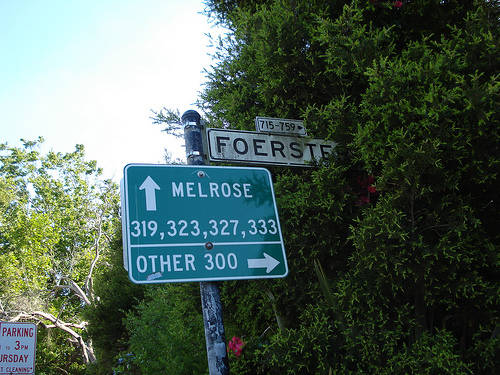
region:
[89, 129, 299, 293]
Large green sign on the pole.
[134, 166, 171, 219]
White arrow on the sign.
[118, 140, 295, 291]
Green sign with white letters.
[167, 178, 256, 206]
White letters on a green sign.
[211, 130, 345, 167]
White sign with black letters.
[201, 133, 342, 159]
Black letters on a white sign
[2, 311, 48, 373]
White sign with red letters.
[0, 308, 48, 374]
Red letters on a white sign.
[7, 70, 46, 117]
Bright blue sky high above.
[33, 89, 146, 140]
Some white clouds in the sky.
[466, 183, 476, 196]
part of a bush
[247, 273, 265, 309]
edge of a post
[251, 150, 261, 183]
part of a sign post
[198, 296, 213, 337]
edge of a post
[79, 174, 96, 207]
part of a cloud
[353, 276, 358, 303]
part of a petal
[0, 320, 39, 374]
red and white parking sign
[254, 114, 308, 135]
white and black street sign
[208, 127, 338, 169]
white and black street sign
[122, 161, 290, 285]
green and white street sign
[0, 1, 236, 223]
partly cloudy blue sky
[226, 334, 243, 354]
pink object on tree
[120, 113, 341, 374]
street signs on a metal post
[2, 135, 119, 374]
tree standing beside signs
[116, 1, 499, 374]
trees standing beside stret signs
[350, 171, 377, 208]
pink object in trees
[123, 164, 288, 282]
a green and white sign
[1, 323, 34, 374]
sign is red and white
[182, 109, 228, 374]
pole made of metal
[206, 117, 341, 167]
a white and black sign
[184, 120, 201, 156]
shiny bands of metal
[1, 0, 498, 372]
trees with green leaves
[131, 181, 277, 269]
the text is white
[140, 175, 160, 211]
the arrow is white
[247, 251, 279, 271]
arrow is pointing left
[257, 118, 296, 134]
numbers on the sign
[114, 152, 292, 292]
Green sign stating Melrose ahead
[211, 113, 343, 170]
white sign with a word on it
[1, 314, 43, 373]
red and white sign telling when parking is allowed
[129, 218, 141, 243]
Number 3 on green sign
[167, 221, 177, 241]
Number 3 on green sign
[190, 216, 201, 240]
Number 3 on green sign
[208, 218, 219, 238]
Number 3 on green sign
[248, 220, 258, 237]
Number 3 on green sign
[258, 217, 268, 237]
Number 3 on green sign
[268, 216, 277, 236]
Number 3 on green sign